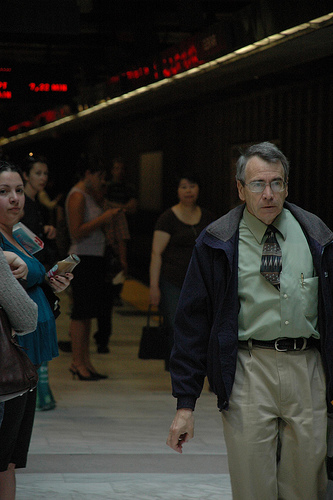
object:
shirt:
[236, 203, 321, 344]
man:
[165, 135, 333, 500]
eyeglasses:
[240, 176, 289, 195]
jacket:
[168, 201, 333, 415]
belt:
[237, 334, 333, 353]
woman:
[64, 144, 121, 385]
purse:
[136, 302, 170, 361]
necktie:
[259, 224, 286, 294]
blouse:
[0, 224, 61, 369]